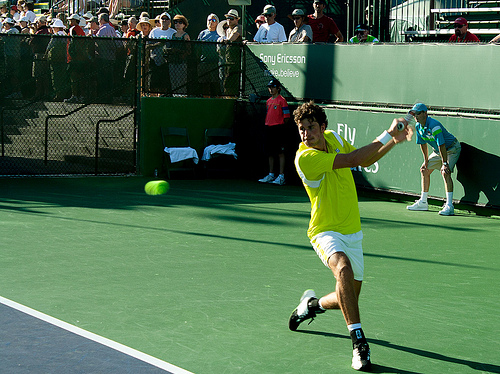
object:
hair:
[292, 99, 329, 131]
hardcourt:
[0, 177, 500, 373]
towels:
[163, 146, 200, 166]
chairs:
[160, 125, 201, 179]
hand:
[387, 116, 409, 137]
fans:
[286, 7, 313, 44]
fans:
[252, 2, 288, 44]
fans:
[219, 8, 242, 95]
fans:
[194, 11, 223, 98]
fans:
[163, 12, 194, 97]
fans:
[144, 11, 177, 98]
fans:
[125, 15, 153, 96]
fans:
[301, 0, 344, 43]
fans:
[346, 23, 380, 44]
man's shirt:
[290, 125, 364, 239]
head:
[292, 99, 329, 148]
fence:
[0, 33, 246, 179]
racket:
[396, 109, 418, 131]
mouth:
[303, 136, 315, 142]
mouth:
[417, 120, 420, 122]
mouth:
[227, 21, 232, 23]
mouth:
[265, 18, 271, 21]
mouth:
[295, 21, 300, 23]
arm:
[300, 129, 393, 171]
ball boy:
[257, 79, 291, 186]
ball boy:
[406, 101, 463, 217]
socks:
[308, 296, 327, 312]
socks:
[347, 322, 366, 339]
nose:
[304, 127, 313, 137]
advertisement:
[259, 52, 305, 78]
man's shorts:
[309, 229, 364, 283]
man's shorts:
[425, 142, 462, 174]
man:
[286, 99, 414, 372]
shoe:
[350, 336, 374, 371]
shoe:
[288, 288, 320, 332]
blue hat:
[408, 102, 428, 114]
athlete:
[286, 96, 414, 372]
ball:
[143, 179, 171, 196]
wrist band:
[375, 129, 393, 146]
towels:
[201, 141, 238, 162]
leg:
[314, 234, 372, 371]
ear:
[320, 123, 325, 134]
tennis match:
[139, 78, 463, 374]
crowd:
[0, 0, 500, 105]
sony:
[259, 53, 276, 66]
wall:
[139, 96, 500, 210]